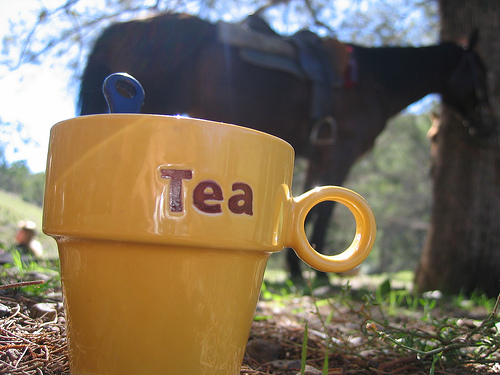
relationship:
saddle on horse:
[206, 19, 365, 147] [70, 9, 497, 288]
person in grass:
[0, 221, 46, 261] [0, 168, 500, 307]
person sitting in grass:
[0, 221, 46, 261] [0, 168, 500, 307]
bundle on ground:
[5, 272, 58, 333] [1, 241, 498, 368]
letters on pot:
[165, 153, 256, 224] [39, 101, 384, 363]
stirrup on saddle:
[311, 116, 339, 150] [206, 19, 365, 147]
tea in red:
[162, 155, 263, 216] [156, 155, 257, 218]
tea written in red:
[162, 155, 263, 216] [156, 155, 257, 218]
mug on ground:
[35, 112, 382, 370] [1, 241, 498, 368]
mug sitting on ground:
[35, 112, 382, 370] [1, 241, 498, 368]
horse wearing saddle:
[70, 9, 497, 288] [206, 19, 365, 147]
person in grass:
[5, 221, 45, 268] [0, 168, 500, 307]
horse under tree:
[70, 9, 497, 288] [5, 8, 499, 315]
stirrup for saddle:
[311, 116, 339, 150] [206, 19, 365, 147]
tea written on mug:
[162, 155, 263, 216] [35, 112, 382, 370]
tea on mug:
[162, 155, 263, 216] [35, 112, 382, 370]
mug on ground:
[35, 112, 382, 374] [1, 241, 498, 368]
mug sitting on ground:
[35, 112, 382, 374] [1, 241, 498, 368]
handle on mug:
[293, 183, 382, 279] [35, 112, 382, 374]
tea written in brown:
[162, 155, 263, 216] [161, 161, 256, 222]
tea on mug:
[162, 155, 263, 216] [35, 112, 382, 374]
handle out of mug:
[102, 67, 148, 111] [35, 112, 382, 374]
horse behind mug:
[70, 9, 497, 288] [35, 112, 382, 374]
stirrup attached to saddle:
[311, 116, 339, 150] [206, 19, 365, 147]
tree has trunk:
[5, 8, 499, 315] [413, 3, 499, 290]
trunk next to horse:
[413, 3, 499, 290] [70, 9, 497, 288]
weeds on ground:
[269, 282, 498, 372] [1, 241, 498, 368]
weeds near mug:
[269, 282, 498, 372] [35, 112, 382, 374]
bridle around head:
[445, 50, 489, 136] [441, 26, 493, 140]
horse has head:
[70, 9, 497, 288] [441, 26, 493, 140]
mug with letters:
[35, 112, 382, 370] [165, 153, 256, 224]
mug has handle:
[35, 112, 382, 370] [102, 67, 148, 111]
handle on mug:
[293, 183, 382, 279] [35, 112, 382, 370]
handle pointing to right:
[293, 183, 382, 279] [251, 0, 497, 370]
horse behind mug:
[70, 9, 497, 288] [35, 112, 382, 370]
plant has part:
[258, 259, 499, 367] [367, 287, 500, 371]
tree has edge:
[5, 8, 499, 315] [8, 0, 440, 94]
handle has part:
[293, 183, 382, 279] [277, 190, 305, 263]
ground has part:
[1, 241, 498, 368] [367, 287, 500, 371]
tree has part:
[5, 8, 499, 315] [4, 0, 353, 93]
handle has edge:
[293, 183, 382, 279] [301, 199, 368, 258]